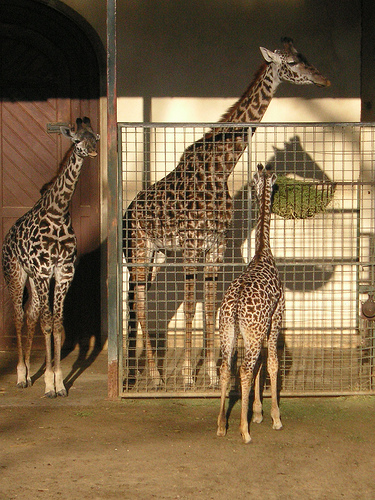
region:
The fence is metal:
[108, 111, 372, 392]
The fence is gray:
[108, 111, 366, 397]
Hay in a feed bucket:
[258, 165, 339, 220]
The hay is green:
[262, 168, 344, 228]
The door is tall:
[2, 7, 119, 356]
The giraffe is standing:
[125, 30, 331, 391]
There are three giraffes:
[12, 28, 330, 428]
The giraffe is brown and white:
[123, 37, 331, 392]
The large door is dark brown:
[5, 5, 116, 353]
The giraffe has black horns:
[74, 109, 97, 135]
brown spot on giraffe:
[60, 224, 64, 233]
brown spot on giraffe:
[42, 239, 51, 250]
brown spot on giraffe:
[32, 257, 42, 266]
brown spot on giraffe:
[254, 328, 262, 338]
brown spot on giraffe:
[250, 340, 256, 346]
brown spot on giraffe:
[250, 345, 253, 349]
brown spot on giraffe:
[259, 293, 264, 298]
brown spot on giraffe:
[265, 308, 270, 314]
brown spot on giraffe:
[246, 312, 254, 324]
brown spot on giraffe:
[244, 330, 250, 340]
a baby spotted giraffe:
[5, 112, 103, 394]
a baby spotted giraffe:
[217, 165, 289, 443]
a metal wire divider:
[116, 119, 373, 395]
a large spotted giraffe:
[123, 40, 324, 386]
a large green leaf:
[263, 172, 331, 220]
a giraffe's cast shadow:
[143, 135, 328, 368]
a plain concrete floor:
[1, 347, 371, 498]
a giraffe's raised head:
[256, 40, 329, 86]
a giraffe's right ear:
[55, 121, 66, 136]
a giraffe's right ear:
[259, 43, 274, 61]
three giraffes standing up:
[24, 10, 354, 461]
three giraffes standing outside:
[25, 46, 374, 476]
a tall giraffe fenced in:
[96, 36, 325, 437]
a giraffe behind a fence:
[130, 17, 346, 370]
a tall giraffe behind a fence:
[97, 15, 302, 499]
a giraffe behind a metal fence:
[91, 29, 322, 418]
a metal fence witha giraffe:
[68, 1, 359, 427]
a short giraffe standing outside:
[95, 128, 365, 479]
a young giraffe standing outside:
[109, 125, 327, 496]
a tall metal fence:
[51, 38, 374, 430]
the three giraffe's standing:
[4, 36, 331, 444]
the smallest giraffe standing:
[217, 162, 282, 442]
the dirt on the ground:
[6, 408, 367, 499]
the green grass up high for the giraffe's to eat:
[261, 174, 319, 212]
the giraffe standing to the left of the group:
[2, 114, 101, 399]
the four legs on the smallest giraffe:
[209, 312, 284, 442]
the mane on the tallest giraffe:
[202, 62, 264, 132]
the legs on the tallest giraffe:
[123, 245, 219, 388]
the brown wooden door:
[1, 99, 96, 337]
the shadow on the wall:
[231, 125, 335, 287]